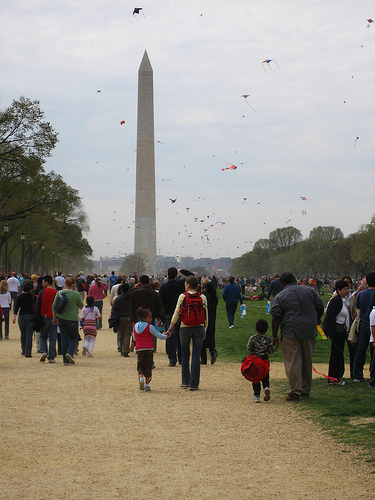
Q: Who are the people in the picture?
A: A mother holding a child's hand.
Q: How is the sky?
A: Full of kites.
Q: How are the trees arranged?
A: In a row.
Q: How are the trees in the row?
A: Green.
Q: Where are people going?
A: Towards a large monument.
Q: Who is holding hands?
A: Woman and little girl.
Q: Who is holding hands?
A: Man and little boy.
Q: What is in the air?
A: Kites.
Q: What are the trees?
A: Varying heights.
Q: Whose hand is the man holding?
A: Boy.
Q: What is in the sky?
A: Kites.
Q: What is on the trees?
A: Leaves.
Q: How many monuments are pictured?
A: One.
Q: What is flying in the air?
A: Kites.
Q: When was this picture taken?
A: During the day.